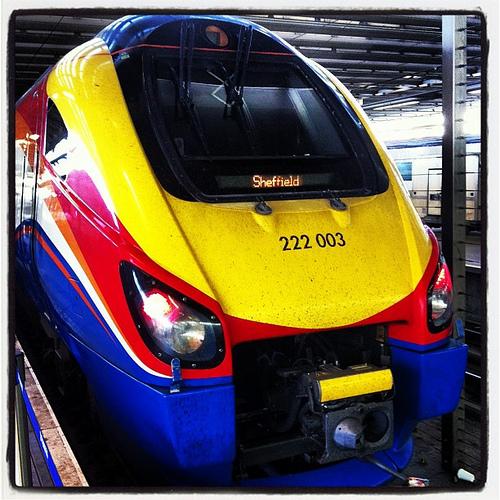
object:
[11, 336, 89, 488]
platform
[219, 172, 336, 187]
sign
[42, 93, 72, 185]
window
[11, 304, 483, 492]
track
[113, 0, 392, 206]
windshield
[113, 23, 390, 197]
window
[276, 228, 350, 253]
numbers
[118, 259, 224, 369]
headlight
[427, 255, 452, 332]
headlight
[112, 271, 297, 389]
light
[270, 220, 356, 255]
222 003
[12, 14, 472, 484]
train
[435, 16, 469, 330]
pole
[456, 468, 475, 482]
cup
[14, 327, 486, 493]
ground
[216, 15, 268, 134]
windshield wiper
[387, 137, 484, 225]
train car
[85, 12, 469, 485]
front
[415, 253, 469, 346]
light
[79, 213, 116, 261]
red